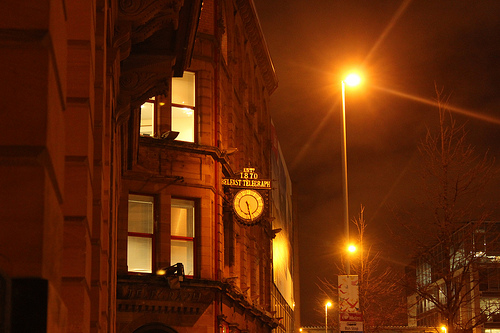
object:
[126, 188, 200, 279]
window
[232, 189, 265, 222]
face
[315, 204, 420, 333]
tree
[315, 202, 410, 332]
bare tree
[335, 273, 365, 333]
sign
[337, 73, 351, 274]
lamp post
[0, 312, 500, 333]
ground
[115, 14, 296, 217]
second story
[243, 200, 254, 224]
clock hands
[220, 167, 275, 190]
sign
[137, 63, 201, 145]
window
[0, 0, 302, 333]
building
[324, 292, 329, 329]
lamp post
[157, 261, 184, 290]
window lights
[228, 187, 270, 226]
clock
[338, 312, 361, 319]
writing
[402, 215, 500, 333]
building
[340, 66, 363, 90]
lights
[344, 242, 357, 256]
lights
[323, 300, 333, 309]
lights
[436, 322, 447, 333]
lights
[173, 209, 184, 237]
light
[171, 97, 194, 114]
lights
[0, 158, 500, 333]
base light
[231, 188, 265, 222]
clock face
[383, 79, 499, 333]
tree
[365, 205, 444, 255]
leaves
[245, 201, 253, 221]
clock hands